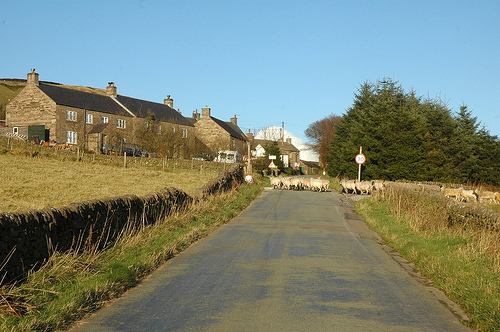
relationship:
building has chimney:
[94, 75, 123, 96] [103, 80, 104, 81]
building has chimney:
[24, 67, 46, 86] [103, 80, 104, 81]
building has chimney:
[160, 90, 178, 108] [103, 80, 104, 81]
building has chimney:
[201, 104, 216, 119] [103, 80, 104, 81]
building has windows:
[94, 75, 123, 96] [64, 111, 80, 126]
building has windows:
[94, 75, 123, 96] [84, 113, 94, 127]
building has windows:
[94, 75, 123, 96] [64, 127, 82, 146]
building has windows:
[94, 75, 123, 96] [114, 117, 129, 131]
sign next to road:
[353, 149, 368, 165] [116, 183, 466, 329]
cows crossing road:
[267, 171, 389, 207] [116, 183, 466, 329]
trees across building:
[330, 78, 482, 177] [24, 67, 46, 86]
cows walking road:
[267, 171, 389, 207] [116, 183, 466, 329]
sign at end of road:
[353, 149, 368, 165] [116, 183, 466, 329]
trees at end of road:
[330, 78, 482, 177] [116, 183, 466, 329]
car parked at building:
[109, 138, 145, 156] [24, 67, 46, 86]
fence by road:
[8, 187, 182, 263] [116, 183, 466, 329]